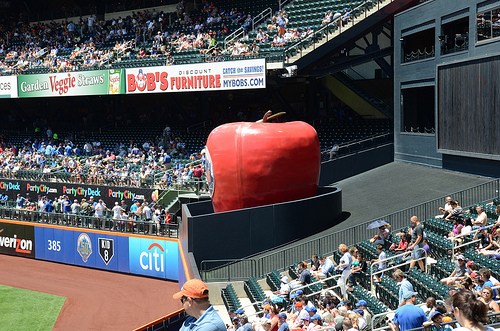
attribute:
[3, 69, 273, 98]
signs — brightly colored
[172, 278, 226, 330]
fan — baseball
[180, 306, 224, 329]
shirt — blue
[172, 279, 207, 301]
cap — orange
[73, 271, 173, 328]
ground — brown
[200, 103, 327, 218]
apple — giant, red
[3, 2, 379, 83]
side — upper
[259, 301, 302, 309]
caps — red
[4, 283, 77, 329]
grass — green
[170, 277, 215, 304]
hat — orange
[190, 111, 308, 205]
bag — red